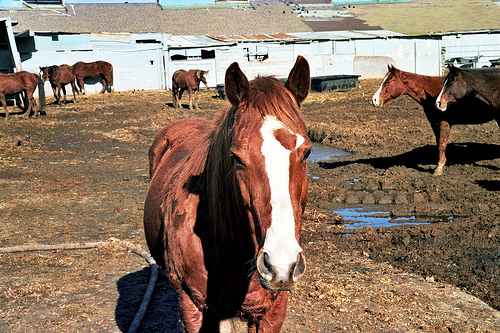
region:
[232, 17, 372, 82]
the house is white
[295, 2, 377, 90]
the house is white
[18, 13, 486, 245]
horses are standing in a pastor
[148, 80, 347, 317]
brown horse with a white stripe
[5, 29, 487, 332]
seven horses are in the picture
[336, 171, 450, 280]
water is on the ground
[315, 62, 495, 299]
horses are standing in mu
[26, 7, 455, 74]
horse stables are beind the pastor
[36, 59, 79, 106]
horse is walking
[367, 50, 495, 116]
light brown horse next to dark brown horse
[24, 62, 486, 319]
horses are standing in dirt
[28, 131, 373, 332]
the ground is brown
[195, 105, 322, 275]
the horse has white spot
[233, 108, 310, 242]
the horse has white spot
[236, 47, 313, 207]
the horse has white spot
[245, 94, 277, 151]
head of a horse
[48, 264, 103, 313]
part of a ground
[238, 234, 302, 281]
nose of a horse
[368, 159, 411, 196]
part of a ground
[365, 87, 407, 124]
mouth of a horse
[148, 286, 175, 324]
part of a shade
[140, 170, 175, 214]
part of a stomach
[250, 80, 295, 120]
part of a horse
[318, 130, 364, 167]
part of a pond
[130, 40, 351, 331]
The horse is brown,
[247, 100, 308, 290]
The horse has a white stripe on his nose.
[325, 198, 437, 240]
A little water puddle.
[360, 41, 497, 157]
Two horses standing next to each other.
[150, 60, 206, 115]
A horse all by himself.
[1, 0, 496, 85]
Buildings in the background.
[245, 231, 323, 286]
The horse has two nostrils.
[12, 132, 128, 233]
Dirt is on the ground.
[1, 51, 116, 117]
Three horse standing near each other.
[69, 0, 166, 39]
The roof of a building.